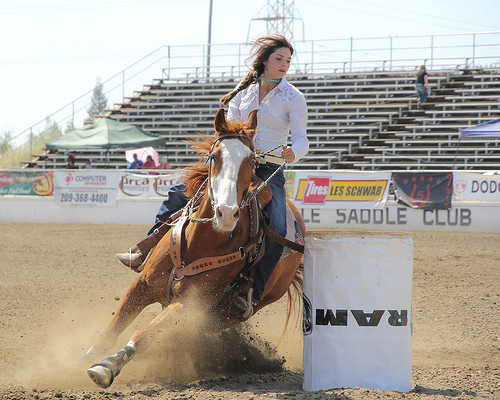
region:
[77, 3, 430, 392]
a woman racing a horse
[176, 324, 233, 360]
dirt flying into the air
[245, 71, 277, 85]
a turquoise necklace around a neck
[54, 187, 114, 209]
a phone number posted on a sign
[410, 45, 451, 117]
a woman walking in the stands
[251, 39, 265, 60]
brown hair blowing in the wind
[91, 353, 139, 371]
black straps on a hoof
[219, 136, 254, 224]
a white patch on a head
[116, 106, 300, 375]
a horse carrying a woman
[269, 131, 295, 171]
a hand grasping the reins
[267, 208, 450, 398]
white sign with black writing.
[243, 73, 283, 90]
Green turqoise necklace on neck.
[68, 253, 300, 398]
Dust from a horses hooves.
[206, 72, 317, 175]
White shirt on a woman.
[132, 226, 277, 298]
Brown bridle on a horse.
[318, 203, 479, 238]
Black letters that say saddle club.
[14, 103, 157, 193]
Green tent in stands.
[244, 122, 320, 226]
Hand holding horses reins.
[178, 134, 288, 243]
Brown and white horse head.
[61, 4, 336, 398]
Woman riding in horse show.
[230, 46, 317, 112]
this is a woman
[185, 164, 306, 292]
this is a horse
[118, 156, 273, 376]
the horse is big in size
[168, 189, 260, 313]
the horse is brown in color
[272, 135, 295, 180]
the hand is holding a rope on the horse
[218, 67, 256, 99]
the woman has long hair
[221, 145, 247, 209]
the horse has white strip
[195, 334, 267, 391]
the soil are splashing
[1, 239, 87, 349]
the ground is brown in color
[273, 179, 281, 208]
the woman is wearing blue trosers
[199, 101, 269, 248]
a horse's head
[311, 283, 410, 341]
the word ram upside down on an obstacle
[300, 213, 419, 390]
an obstacle for the horse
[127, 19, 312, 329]
a female horse jockey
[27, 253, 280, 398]
the dust being kicked up by the horse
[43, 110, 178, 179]
a tent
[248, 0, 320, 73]
an electrical tower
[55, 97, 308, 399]
a horse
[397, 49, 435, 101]
a person walking up the bleachers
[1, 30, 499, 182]
the bleachers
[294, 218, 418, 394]
A white barrel with the RAM logo on it.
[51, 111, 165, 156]
A large green tent with people under it.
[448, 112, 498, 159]
A blue tent in the bleachers.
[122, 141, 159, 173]
A red umbrella in the bleachers.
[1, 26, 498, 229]
Empty bleachers with several rows of benches.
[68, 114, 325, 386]
A running brown and white horse.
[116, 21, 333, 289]
A woman riding a running horse.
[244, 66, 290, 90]
A turquoise necklace on the woman.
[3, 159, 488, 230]
Advertisements hanging on the wall.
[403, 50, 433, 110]
A woman in a black shirt walking up the stairs.